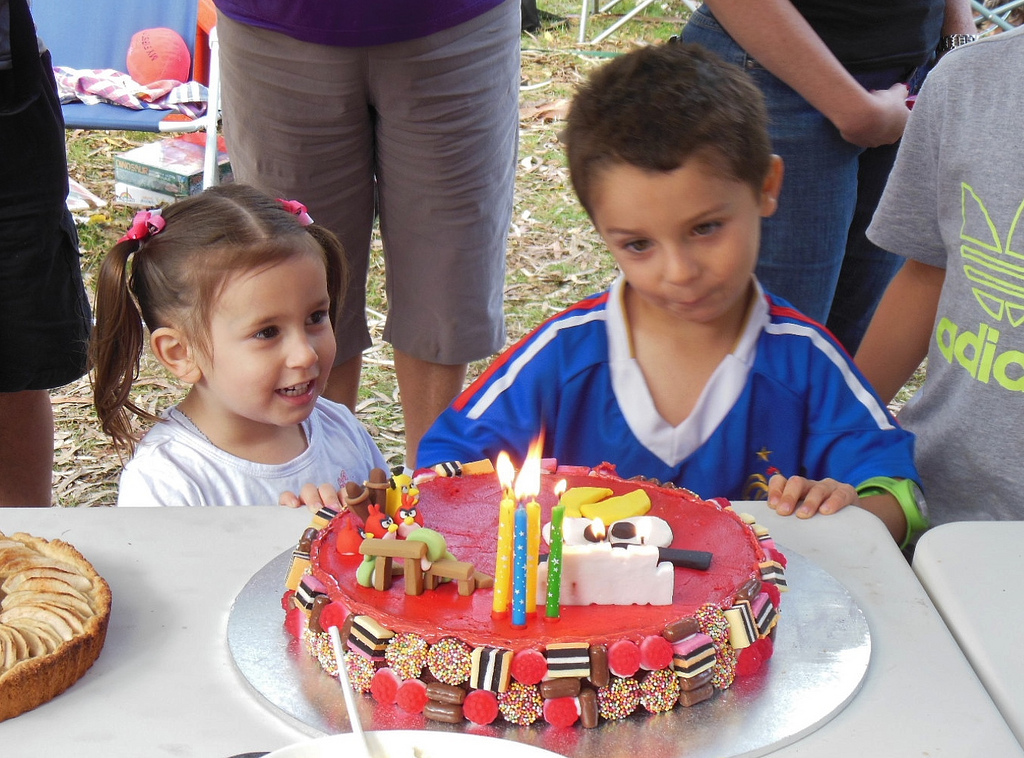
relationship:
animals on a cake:
[323, 438, 678, 711] [250, 336, 860, 736]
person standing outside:
[452, 49, 857, 528] [129, 14, 908, 448]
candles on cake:
[542, 470, 566, 623] [284, 452, 779, 756]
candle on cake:
[510, 501, 529, 628] [284, 452, 779, 756]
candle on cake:
[480, 490, 519, 607] [260, 431, 846, 735]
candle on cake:
[524, 434, 541, 611] [284, 452, 779, 756]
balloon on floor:
[127, 27, 208, 89] [55, 1, 975, 508]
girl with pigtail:
[88, 182, 406, 503] [80, 209, 169, 448]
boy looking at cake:
[408, 35, 928, 528] [284, 452, 779, 756]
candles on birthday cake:
[483, 453, 569, 615] [278, 451, 784, 726]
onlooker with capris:
[238, 0, 527, 479] [212, 1, 525, 385]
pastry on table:
[0, 533, 115, 723] [0, 504, 1019, 755]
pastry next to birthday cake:
[0, 533, 115, 723] [278, 451, 784, 726]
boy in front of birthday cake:
[408, 109, 927, 489] [262, 413, 794, 712]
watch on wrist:
[853, 465, 931, 529] [842, 467, 936, 528]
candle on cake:
[525, 434, 542, 611] [343, 381, 873, 727]